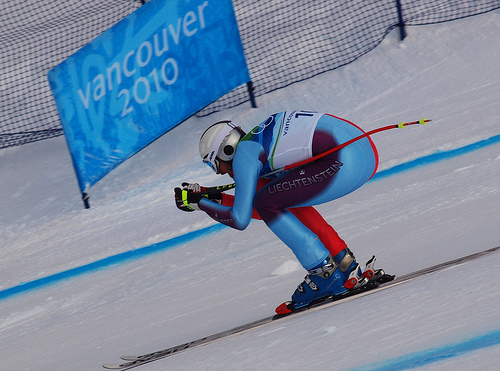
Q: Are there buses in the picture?
A: No, there are no buses.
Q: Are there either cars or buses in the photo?
A: No, there are no buses or cars.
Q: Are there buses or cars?
A: No, there are no buses or cars.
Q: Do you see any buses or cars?
A: No, there are no buses or cars.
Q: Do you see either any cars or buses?
A: No, there are no buses or cars.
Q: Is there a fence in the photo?
A: Yes, there is a fence.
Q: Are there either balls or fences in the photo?
A: Yes, there is a fence.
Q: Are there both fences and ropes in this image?
A: No, there is a fence but no ropes.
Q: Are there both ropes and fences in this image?
A: No, there is a fence but no ropes.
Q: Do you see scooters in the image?
A: No, there are no scooters.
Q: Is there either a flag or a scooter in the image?
A: No, there are no scooters or flags.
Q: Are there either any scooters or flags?
A: No, there are no scooters or flags.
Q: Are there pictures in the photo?
A: No, there are no pictures.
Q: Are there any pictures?
A: No, there are no pictures.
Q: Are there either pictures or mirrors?
A: No, there are no pictures or mirrors.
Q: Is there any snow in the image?
A: Yes, there is snow.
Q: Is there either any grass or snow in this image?
A: Yes, there is snow.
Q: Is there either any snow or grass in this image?
A: Yes, there is snow.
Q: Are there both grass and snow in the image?
A: No, there is snow but no grass.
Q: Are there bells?
A: No, there are no bells.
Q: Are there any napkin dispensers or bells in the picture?
A: No, there are no bells or napkin dispensers.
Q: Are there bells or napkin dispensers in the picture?
A: No, there are no bells or napkin dispensers.